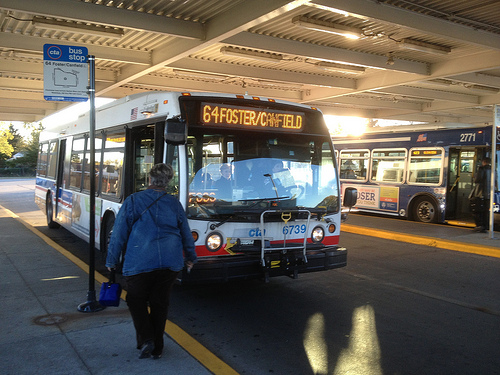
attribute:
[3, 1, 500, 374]
photo — daytime, buses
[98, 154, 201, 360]
woman — walking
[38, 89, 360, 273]
bus — #6739, blue, parked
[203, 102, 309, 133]
foster/canfield — digital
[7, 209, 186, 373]
sidewalk — concrete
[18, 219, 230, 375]
curb — yellow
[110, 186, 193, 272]
coat — blue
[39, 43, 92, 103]
sign — blue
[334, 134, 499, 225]
bus — blue, #2771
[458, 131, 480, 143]
numbers — white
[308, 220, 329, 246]
headlights — round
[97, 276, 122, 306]
bag — blue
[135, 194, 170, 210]
strap — black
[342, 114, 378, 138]
sun — shineing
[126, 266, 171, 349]
pants — black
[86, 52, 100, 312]
pole — metal